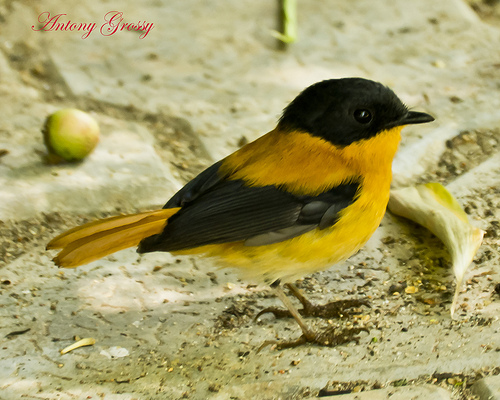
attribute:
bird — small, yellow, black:
[44, 78, 435, 351]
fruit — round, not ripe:
[42, 108, 100, 161]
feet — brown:
[255, 297, 372, 351]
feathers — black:
[137, 157, 363, 256]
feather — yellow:
[46, 206, 182, 270]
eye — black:
[355, 107, 372, 125]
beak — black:
[401, 111, 434, 126]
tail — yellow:
[46, 207, 180, 269]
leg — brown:
[275, 290, 307, 334]